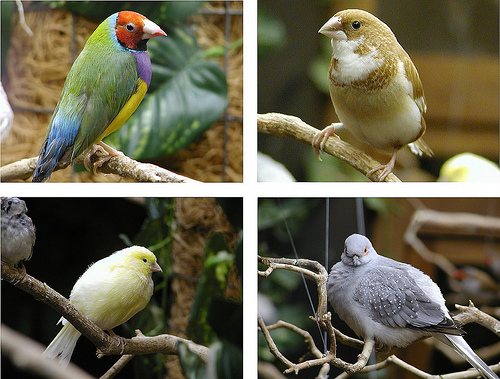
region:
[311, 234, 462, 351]
the birs is perched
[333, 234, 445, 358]
the feathers are grey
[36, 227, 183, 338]
the bird is perched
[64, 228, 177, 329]
the bird is yellow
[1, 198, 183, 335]
two birds are perched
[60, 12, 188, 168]
the bird is perched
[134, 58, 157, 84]
the feather is pruprle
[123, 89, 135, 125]
the feathers are yellow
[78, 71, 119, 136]
the wing is green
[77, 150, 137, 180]
the tallons are sharp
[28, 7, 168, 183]
multi-colored bird on branch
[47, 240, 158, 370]
yellow bird on branch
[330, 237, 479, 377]
grey bird on branch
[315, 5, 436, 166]
brown and white bird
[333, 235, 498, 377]
pigeon standing on branch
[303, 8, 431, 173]
bird with tan beak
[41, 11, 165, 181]
bird with red beak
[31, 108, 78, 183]
blue tail feathers on bird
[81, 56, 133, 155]
green wing on bird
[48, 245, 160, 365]
canary sitting on branch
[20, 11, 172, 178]
Multicolored bird on branch.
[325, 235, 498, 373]
Grey bird on branch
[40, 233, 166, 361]
Light yellow bird on branch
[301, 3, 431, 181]
Light brown and cream colored bird on branch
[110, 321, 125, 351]
Claw of light yellow bird.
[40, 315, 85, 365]
Tail of light yellow bird.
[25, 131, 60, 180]
Tail of multicolored bird.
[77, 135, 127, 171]
Claws of multicolored bird.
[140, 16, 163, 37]
Beak of multicolored bird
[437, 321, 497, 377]
Tail of grey colored bird.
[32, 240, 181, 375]
a small yellow bird.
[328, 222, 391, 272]
a bird with a gray head.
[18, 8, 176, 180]
A colorful bird.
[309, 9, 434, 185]
a brown and white bird.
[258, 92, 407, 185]
a brown tree branch.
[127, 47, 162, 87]
purple feathers on a bird.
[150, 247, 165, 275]
a beak on a bird.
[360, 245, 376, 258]
the left eye of a bird.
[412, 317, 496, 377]
a set of gray tail feathers.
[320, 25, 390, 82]
a bird with white feathers.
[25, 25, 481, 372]
numerous birds sitting on branches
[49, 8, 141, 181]
tropical bird has multicolor body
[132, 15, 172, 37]
bird has pink beak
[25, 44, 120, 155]
bird has green body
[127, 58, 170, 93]
bird has purple patch on breast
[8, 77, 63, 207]
bird has blue tail feathers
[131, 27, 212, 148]
green leaf is behind colorful bird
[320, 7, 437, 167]
brown bird has white beak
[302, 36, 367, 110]
white patch on brown bird's neck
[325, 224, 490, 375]
large and round lavender colored bird